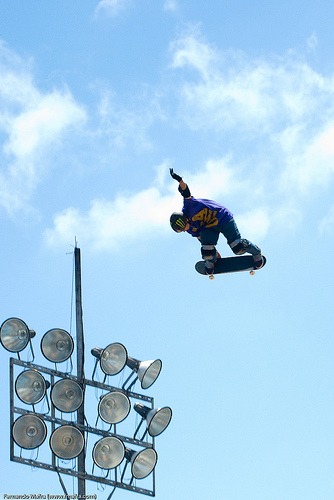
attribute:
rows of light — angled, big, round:
[3, 315, 173, 499]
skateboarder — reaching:
[166, 168, 268, 278]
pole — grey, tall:
[73, 245, 88, 499]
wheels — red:
[206, 269, 256, 278]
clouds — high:
[2, 2, 334, 284]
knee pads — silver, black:
[198, 243, 250, 260]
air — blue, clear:
[2, 2, 332, 500]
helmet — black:
[169, 213, 184, 234]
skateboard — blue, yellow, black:
[193, 254, 266, 279]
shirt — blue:
[182, 196, 229, 233]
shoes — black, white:
[204, 248, 263, 269]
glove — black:
[167, 166, 180, 178]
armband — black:
[178, 186, 192, 199]